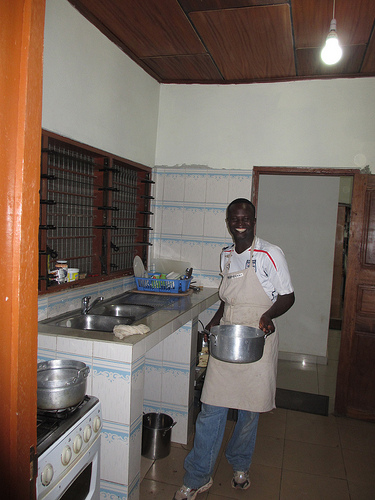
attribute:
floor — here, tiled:
[118, 385, 373, 499]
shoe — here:
[230, 466, 254, 491]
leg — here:
[186, 388, 222, 488]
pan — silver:
[211, 323, 263, 364]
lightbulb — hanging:
[312, 30, 346, 67]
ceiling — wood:
[87, 1, 373, 87]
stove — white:
[40, 360, 111, 500]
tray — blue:
[135, 261, 199, 295]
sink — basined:
[78, 294, 154, 333]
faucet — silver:
[77, 292, 106, 313]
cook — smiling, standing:
[182, 191, 287, 495]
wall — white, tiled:
[155, 85, 374, 384]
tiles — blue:
[150, 162, 250, 282]